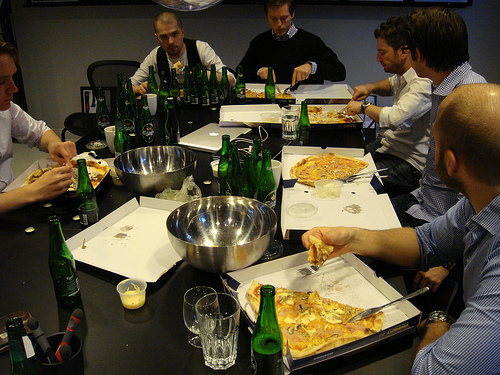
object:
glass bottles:
[47, 158, 99, 308]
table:
[0, 83, 421, 375]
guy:
[0, 42, 77, 215]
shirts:
[375, 61, 500, 375]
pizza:
[246, 279, 384, 360]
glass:
[195, 292, 242, 370]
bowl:
[165, 195, 278, 274]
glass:
[182, 285, 220, 349]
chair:
[61, 60, 142, 143]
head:
[431, 82, 500, 191]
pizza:
[289, 152, 370, 188]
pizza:
[307, 106, 357, 125]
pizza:
[245, 88, 294, 98]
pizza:
[24, 159, 111, 191]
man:
[300, 82, 500, 375]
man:
[367, 8, 489, 279]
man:
[343, 15, 432, 192]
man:
[124, 11, 238, 96]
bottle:
[256, 149, 276, 209]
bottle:
[250, 284, 284, 375]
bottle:
[264, 66, 276, 104]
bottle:
[113, 118, 133, 159]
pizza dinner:
[0, 54, 428, 375]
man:
[235, 1, 347, 87]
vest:
[156, 38, 204, 93]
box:
[220, 250, 423, 372]